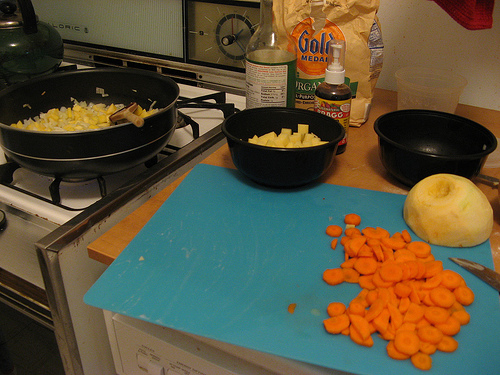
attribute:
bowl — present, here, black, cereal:
[225, 106, 319, 203]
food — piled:
[348, 221, 442, 345]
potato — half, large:
[410, 183, 475, 219]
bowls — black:
[238, 107, 458, 188]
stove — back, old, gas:
[23, 171, 129, 224]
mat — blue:
[204, 187, 359, 290]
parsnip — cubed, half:
[403, 169, 484, 228]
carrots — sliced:
[353, 235, 459, 367]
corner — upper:
[79, 218, 128, 268]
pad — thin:
[155, 203, 278, 274]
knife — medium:
[452, 254, 498, 289]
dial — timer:
[215, 13, 251, 54]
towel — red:
[449, 4, 500, 38]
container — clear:
[248, 16, 291, 74]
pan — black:
[85, 150, 140, 173]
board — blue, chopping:
[284, 200, 316, 244]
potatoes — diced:
[261, 126, 322, 167]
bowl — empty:
[379, 102, 475, 170]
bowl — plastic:
[392, 63, 491, 118]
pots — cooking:
[48, 69, 169, 164]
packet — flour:
[297, 17, 392, 83]